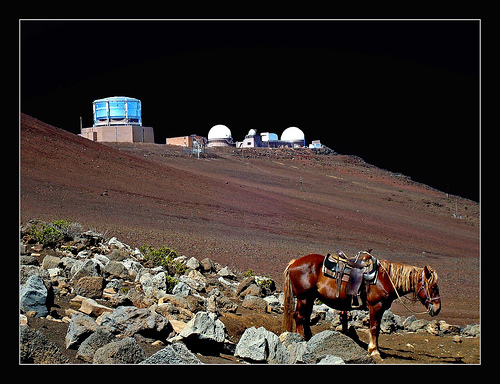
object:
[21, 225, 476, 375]
rock pile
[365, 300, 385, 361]
leg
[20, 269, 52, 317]
bad rocks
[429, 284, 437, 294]
eye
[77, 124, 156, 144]
building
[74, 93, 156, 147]
buildings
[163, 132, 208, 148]
buildings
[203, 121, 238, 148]
buildings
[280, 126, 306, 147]
buildings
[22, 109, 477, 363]
hill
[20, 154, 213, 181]
ground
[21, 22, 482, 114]
sky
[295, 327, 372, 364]
rock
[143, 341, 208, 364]
rock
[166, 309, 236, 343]
rock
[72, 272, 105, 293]
rock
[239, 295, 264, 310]
rock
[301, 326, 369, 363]
rocks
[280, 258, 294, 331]
tail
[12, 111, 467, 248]
dirt hill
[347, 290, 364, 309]
stirrups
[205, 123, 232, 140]
globe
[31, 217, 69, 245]
grass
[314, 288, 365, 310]
stomach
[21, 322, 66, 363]
rocks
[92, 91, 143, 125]
boiler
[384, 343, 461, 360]
shadow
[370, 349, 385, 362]
hoof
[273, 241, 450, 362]
horse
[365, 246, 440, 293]
blonde hair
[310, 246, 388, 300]
saddle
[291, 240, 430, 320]
horse's back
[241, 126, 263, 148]
building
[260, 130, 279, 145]
building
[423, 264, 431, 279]
ear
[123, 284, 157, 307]
rocks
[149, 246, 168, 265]
bushes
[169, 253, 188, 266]
rocks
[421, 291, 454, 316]
harness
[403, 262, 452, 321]
face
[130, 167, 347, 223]
red dirt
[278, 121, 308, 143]
globe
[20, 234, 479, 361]
ground